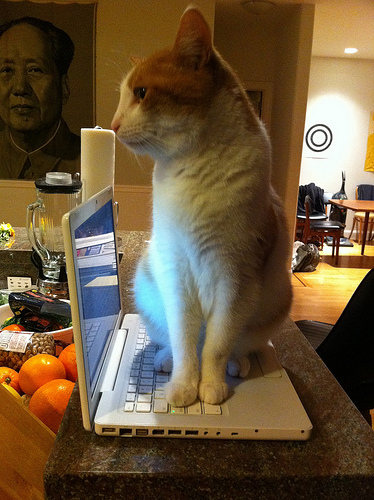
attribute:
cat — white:
[109, 6, 297, 411]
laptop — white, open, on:
[55, 183, 316, 445]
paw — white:
[197, 375, 233, 409]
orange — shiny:
[17, 351, 68, 398]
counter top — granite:
[37, 310, 370, 500]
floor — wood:
[289, 239, 373, 325]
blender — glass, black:
[7, 165, 86, 335]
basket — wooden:
[2, 375, 66, 499]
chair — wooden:
[302, 188, 347, 266]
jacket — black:
[301, 180, 326, 220]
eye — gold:
[127, 84, 154, 108]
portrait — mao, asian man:
[2, 2, 100, 182]